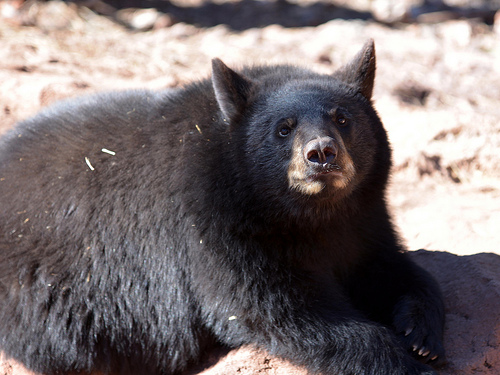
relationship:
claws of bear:
[405, 327, 440, 360] [14, 33, 441, 373]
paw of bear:
[363, 318, 442, 375] [14, 33, 441, 373]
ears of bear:
[207, 35, 384, 125] [10, 55, 472, 337]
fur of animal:
[23, 137, 165, 220] [16, 44, 426, 341]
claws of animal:
[408, 329, 441, 363] [1, 38, 455, 373]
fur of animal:
[23, 137, 165, 220] [1, 38, 455, 373]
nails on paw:
[402, 328, 438, 361] [395, 302, 447, 365]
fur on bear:
[87, 218, 194, 370] [4, 41, 461, 367]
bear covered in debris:
[4, 41, 461, 367] [42, 130, 158, 184]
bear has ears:
[4, 41, 461, 367] [332, 37, 374, 102]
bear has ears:
[4, 41, 461, 367] [212, 56, 257, 126]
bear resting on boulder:
[0, 38, 445, 375] [192, 245, 497, 373]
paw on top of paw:
[369, 313, 480, 374] [343, 326, 416, 373]